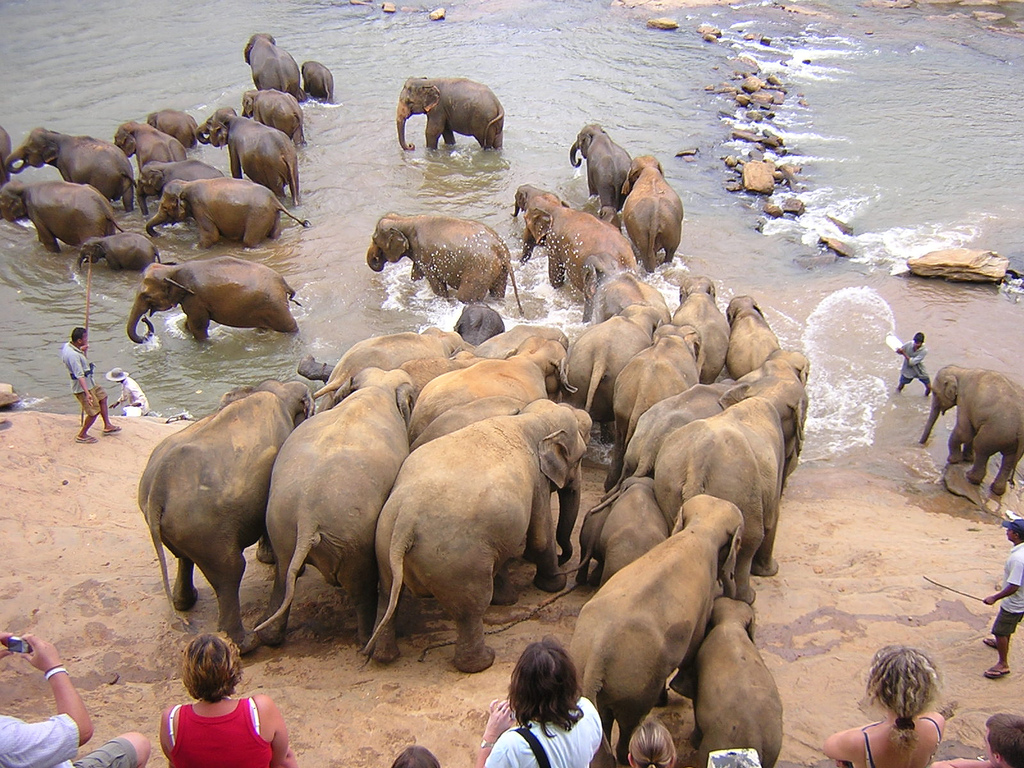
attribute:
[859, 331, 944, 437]
trainer — encouraging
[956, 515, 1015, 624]
trainer — guiding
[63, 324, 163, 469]
trainer — guiding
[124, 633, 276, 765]
tourist — observing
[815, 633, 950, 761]
tourist — observing, curly haired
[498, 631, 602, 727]
woman — dark haired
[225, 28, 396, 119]
elephant — mommy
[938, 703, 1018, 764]
man — brown haired, observing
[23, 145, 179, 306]
elephant — large, grey